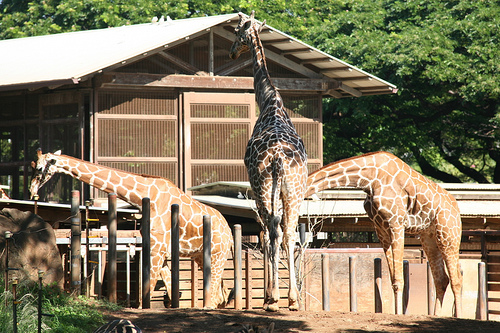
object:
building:
[0, 12, 402, 196]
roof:
[0, 11, 401, 96]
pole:
[170, 204, 180, 311]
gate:
[181, 92, 256, 199]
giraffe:
[229, 18, 308, 310]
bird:
[284, 8, 293, 16]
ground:
[0, 283, 500, 333]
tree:
[0, 0, 498, 183]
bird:
[150, 16, 158, 25]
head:
[229, 18, 258, 60]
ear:
[242, 20, 252, 30]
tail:
[269, 163, 283, 267]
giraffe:
[29, 146, 235, 309]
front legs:
[149, 245, 172, 311]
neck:
[251, 44, 284, 112]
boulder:
[0, 207, 65, 305]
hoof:
[266, 306, 280, 312]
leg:
[392, 229, 405, 316]